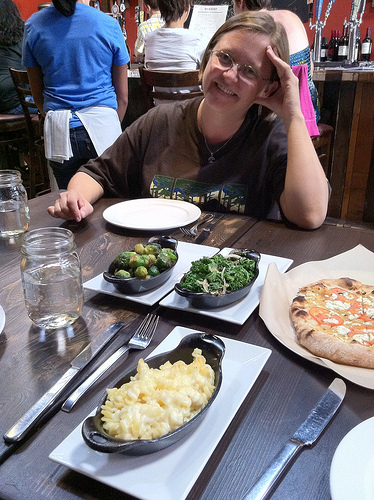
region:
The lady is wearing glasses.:
[200, 48, 264, 91]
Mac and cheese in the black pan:
[90, 358, 216, 428]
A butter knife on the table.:
[265, 376, 303, 497]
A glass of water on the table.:
[22, 220, 83, 328]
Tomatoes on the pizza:
[296, 269, 362, 347]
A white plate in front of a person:
[93, 179, 193, 242]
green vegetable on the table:
[126, 238, 158, 277]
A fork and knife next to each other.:
[37, 307, 155, 360]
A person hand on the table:
[47, 168, 120, 209]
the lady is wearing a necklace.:
[199, 118, 238, 163]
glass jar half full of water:
[19, 225, 84, 330]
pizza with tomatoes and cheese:
[289, 275, 373, 369]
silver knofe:
[242, 375, 346, 497]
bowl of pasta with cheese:
[80, 329, 228, 457]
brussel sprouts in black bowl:
[98, 233, 179, 298]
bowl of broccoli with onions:
[174, 246, 261, 309]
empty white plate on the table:
[101, 193, 201, 233]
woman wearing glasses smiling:
[48, 11, 336, 231]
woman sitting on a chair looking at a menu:
[140, 0, 229, 115]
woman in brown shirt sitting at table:
[1, 10, 373, 498]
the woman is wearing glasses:
[210, 46, 267, 86]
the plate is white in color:
[102, 199, 201, 228]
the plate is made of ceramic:
[103, 196, 198, 229]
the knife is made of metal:
[241, 381, 355, 496]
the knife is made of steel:
[239, 375, 355, 497]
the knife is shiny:
[239, 375, 348, 496]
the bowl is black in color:
[85, 325, 227, 465]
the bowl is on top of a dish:
[85, 328, 227, 461]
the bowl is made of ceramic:
[83, 333, 230, 459]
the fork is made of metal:
[66, 316, 164, 408]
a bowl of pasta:
[77, 328, 231, 465]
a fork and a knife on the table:
[3, 311, 162, 450]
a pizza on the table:
[287, 269, 373, 379]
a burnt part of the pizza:
[293, 293, 307, 302]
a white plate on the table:
[100, 197, 203, 230]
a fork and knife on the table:
[177, 211, 233, 245]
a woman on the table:
[45, 6, 333, 237]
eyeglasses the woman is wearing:
[205, 46, 263, 87]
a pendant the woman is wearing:
[205, 151, 216, 164]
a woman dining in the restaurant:
[2, 10, 373, 490]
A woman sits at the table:
[59, 19, 342, 250]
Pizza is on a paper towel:
[278, 230, 372, 377]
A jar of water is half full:
[10, 220, 97, 332]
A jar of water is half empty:
[18, 226, 90, 336]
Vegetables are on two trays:
[94, 224, 263, 313]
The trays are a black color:
[97, 221, 264, 313]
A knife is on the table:
[239, 370, 358, 497]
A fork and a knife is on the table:
[6, 308, 167, 445]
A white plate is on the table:
[103, 190, 198, 236]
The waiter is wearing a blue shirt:
[16, 4, 129, 132]